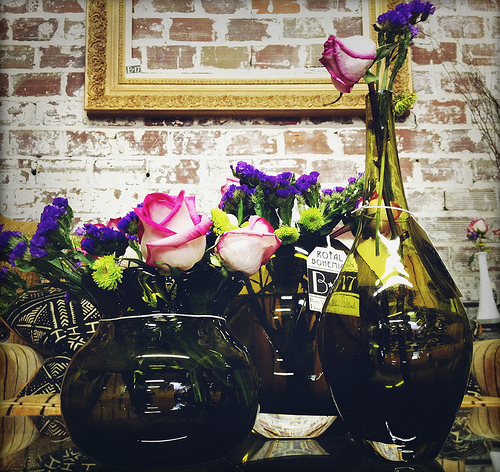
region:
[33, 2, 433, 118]
gold frame showing exposed brick wall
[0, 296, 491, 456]
yellow couch with black lines behind flowers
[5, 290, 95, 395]
black pillow with white designs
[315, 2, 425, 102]
dried flowers sticking out of tall curved vase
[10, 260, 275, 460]
short and round vase of dark glass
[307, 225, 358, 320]
black and white tag hanging from container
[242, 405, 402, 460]
vases and table showing bright reflections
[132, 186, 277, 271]
pale roses edged in pink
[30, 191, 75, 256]
small purple flowers on long stems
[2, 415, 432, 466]
dark and shiny reflective table surface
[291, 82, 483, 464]
a green glass vase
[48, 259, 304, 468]
a dark green glass vase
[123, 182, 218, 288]
a white and red rose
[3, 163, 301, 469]
several flowers in a vase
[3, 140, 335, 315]
blue, red, yellow, and white flowers in a vase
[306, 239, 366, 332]
a black and white tag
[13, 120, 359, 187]
a brick wall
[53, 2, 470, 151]
an empty frame on a brick wall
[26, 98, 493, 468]
two green vases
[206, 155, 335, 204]
blue and green flowers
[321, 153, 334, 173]
edge of a wall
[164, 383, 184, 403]
part of a bulb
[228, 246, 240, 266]
part of a flower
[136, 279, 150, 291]
part of a stem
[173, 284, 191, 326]
edge of a flower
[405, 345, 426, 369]
side of a vase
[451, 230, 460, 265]
part of a wall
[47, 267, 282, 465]
short, fat, dark vase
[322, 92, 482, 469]
tall and thin vase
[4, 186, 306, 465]
flowers in the vase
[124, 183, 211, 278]
pink rose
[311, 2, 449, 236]
rose leaning over the mouth of the vase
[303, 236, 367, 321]
black and white tag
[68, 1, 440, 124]
gold frame with nothing in it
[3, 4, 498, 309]
distressed brick wall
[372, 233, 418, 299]
light gleaming on the vase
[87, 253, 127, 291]
small yellow flower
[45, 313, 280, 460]
the vase is glass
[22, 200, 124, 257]
the flowers are purple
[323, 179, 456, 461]
the vase is tinted green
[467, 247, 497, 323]
the vase is white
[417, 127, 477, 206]
the wall is brick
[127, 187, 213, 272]
the flower is white with pink tips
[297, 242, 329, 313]
the tag is white and black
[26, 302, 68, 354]
the pillows are black and tan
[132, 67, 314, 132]
the frame is golden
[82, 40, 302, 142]
the frame is on the wall